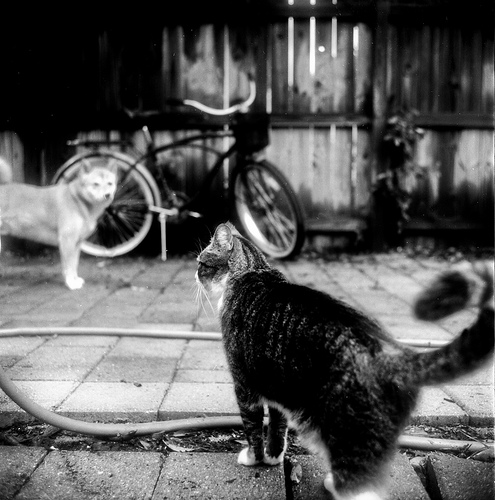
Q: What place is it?
A: It is a patio.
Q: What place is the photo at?
A: It is at the patio.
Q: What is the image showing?
A: It is showing a patio.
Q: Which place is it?
A: It is a patio.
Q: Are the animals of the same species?
A: No, they are dogs and cats.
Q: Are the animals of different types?
A: Yes, they are dogs and cats.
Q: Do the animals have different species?
A: Yes, they are dogs and cats.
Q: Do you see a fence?
A: Yes, there is a fence.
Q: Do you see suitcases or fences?
A: Yes, there is a fence.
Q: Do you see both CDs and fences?
A: No, there is a fence but no cds.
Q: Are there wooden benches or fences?
A: Yes, there is a wood fence.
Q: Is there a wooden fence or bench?
A: Yes, there is a wood fence.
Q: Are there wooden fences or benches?
A: Yes, there is a wood fence.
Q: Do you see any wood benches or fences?
A: Yes, there is a wood fence.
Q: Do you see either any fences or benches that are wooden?
A: Yes, the fence is wooden.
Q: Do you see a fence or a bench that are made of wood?
A: Yes, the fence is made of wood.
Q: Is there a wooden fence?
A: Yes, there is a wood fence.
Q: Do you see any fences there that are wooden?
A: Yes, there is a fence that is wooden.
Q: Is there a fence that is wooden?
A: Yes, there is a fence that is wooden.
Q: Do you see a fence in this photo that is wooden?
A: Yes, there is a fence that is wooden.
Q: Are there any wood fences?
A: Yes, there is a fence that is made of wood.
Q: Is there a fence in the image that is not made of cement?
A: Yes, there is a fence that is made of wood.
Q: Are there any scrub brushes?
A: No, there are no scrub brushes.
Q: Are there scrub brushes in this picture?
A: No, there are no scrub brushes.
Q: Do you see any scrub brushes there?
A: No, there are no scrub brushes.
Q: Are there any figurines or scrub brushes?
A: No, there are no scrub brushes or figurines.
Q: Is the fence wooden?
A: Yes, the fence is wooden.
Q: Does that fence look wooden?
A: Yes, the fence is wooden.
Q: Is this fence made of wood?
A: Yes, the fence is made of wood.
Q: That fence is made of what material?
A: The fence is made of wood.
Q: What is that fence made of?
A: The fence is made of wood.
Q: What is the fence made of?
A: The fence is made of wood.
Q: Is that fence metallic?
A: No, the fence is wooden.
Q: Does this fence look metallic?
A: No, the fence is wooden.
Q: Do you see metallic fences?
A: No, there is a fence but it is wooden.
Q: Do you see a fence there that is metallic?
A: No, there is a fence but it is wooden.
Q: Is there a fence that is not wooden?
A: No, there is a fence but it is wooden.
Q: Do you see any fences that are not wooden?
A: No, there is a fence but it is wooden.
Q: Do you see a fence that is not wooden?
A: No, there is a fence but it is wooden.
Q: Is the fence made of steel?
A: No, the fence is made of wood.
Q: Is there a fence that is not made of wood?
A: No, there is a fence but it is made of wood.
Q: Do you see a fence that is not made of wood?
A: No, there is a fence but it is made of wood.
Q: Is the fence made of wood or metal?
A: The fence is made of wood.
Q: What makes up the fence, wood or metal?
A: The fence is made of wood.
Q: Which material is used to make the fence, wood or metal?
A: The fence is made of wood.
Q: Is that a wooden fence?
A: Yes, that is a wooden fence.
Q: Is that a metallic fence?
A: No, that is a wooden fence.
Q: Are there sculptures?
A: No, there are no sculptures.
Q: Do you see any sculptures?
A: No, there are no sculptures.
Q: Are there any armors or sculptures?
A: No, there are no sculptures or armors.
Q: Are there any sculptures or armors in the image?
A: No, there are no sculptures or armors.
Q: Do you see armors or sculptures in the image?
A: No, there are no sculptures or armors.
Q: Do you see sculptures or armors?
A: No, there are no sculptures or armors.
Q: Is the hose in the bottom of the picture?
A: Yes, the hose is in the bottom of the image.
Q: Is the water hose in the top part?
A: No, the water hose is in the bottom of the image.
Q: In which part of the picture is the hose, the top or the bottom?
A: The hose is in the bottom of the image.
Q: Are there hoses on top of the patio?
A: Yes, there is a hose on top of the patio.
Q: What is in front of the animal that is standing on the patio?
A: The hose is in front of the cat.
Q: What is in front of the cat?
A: The hose is in front of the cat.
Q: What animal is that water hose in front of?
A: The water hose is in front of the cat.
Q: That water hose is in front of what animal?
A: The water hose is in front of the cat.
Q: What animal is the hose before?
A: The water hose is in front of the cat.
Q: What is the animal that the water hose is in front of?
A: The animal is a cat.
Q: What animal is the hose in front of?
A: The water hose is in front of the cat.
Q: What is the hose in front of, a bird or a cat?
A: The hose is in front of a cat.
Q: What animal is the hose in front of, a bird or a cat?
A: The hose is in front of a cat.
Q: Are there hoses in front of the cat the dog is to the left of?
A: Yes, there is a hose in front of the cat.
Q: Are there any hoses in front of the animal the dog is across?
A: Yes, there is a hose in front of the cat.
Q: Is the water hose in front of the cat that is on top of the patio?
A: Yes, the water hose is in front of the cat.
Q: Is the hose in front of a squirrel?
A: No, the hose is in front of the cat.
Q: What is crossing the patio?
A: The water hose is crossing the patio.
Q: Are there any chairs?
A: No, there are no chairs.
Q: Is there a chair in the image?
A: No, there are no chairs.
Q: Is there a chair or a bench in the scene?
A: No, there are no chairs or benches.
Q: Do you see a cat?
A: Yes, there is a cat.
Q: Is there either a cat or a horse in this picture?
A: Yes, there is a cat.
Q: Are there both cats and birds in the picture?
A: No, there is a cat but no birds.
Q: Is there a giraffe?
A: No, there are no giraffes.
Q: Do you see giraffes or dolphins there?
A: No, there are no giraffes or dolphins.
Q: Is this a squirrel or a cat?
A: This is a cat.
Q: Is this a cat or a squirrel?
A: This is a cat.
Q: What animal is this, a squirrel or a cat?
A: This is a cat.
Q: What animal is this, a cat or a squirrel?
A: This is a cat.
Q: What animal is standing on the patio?
A: The cat is standing on the patio.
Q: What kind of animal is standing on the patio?
A: The animal is a cat.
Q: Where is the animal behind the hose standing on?
A: The cat is standing on the patio.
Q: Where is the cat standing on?
A: The cat is standing on the patio.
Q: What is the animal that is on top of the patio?
A: The animal is a cat.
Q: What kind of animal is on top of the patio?
A: The animal is a cat.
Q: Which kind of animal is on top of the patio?
A: The animal is a cat.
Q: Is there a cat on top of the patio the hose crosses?
A: Yes, there is a cat on top of the patio.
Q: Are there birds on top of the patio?
A: No, there is a cat on top of the patio.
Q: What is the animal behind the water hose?
A: The animal is a cat.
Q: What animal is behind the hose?
A: The animal is a cat.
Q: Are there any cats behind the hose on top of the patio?
A: Yes, there is a cat behind the water hose.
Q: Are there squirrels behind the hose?
A: No, there is a cat behind the hose.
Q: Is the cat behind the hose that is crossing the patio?
A: Yes, the cat is behind the water hose.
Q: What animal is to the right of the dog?
A: The animal is a cat.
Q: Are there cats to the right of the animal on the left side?
A: Yes, there is a cat to the right of the dog.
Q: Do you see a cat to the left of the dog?
A: No, the cat is to the right of the dog.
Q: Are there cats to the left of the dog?
A: No, the cat is to the right of the dog.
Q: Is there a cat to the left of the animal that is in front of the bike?
A: No, the cat is to the right of the dog.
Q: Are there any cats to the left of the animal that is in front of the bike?
A: No, the cat is to the right of the dog.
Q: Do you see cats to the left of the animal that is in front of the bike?
A: No, the cat is to the right of the dog.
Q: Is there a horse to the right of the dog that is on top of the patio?
A: No, there is a cat to the right of the dog.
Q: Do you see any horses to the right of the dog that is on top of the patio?
A: No, there is a cat to the right of the dog.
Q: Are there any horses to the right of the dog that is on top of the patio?
A: No, there is a cat to the right of the dog.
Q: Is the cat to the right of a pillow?
A: No, the cat is to the right of the dog.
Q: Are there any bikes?
A: Yes, there is a bike.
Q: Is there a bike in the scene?
A: Yes, there is a bike.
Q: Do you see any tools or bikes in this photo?
A: Yes, there is a bike.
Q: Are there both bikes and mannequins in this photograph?
A: No, there is a bike but no mannequins.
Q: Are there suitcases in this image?
A: No, there are no suitcases.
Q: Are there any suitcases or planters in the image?
A: No, there are no suitcases or planters.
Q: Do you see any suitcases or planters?
A: No, there are no suitcases or planters.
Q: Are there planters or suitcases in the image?
A: No, there are no suitcases or planters.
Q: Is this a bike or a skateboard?
A: This is a bike.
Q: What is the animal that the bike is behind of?
A: The animal is a dog.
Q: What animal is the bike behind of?
A: The bike is behind the dog.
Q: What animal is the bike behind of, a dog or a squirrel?
A: The bike is behind a dog.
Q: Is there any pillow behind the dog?
A: No, there is a bike behind the dog.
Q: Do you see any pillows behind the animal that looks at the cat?
A: No, there is a bike behind the dog.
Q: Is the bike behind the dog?
A: Yes, the bike is behind the dog.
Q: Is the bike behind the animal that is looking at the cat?
A: Yes, the bike is behind the dog.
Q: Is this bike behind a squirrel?
A: No, the bike is behind the dog.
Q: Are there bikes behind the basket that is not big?
A: Yes, there is a bike behind the basket.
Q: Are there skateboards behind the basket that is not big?
A: No, there is a bike behind the basket.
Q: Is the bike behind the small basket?
A: Yes, the bike is behind the basket.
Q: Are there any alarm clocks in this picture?
A: No, there are no alarm clocks.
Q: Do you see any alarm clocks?
A: No, there are no alarm clocks.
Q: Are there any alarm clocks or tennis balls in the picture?
A: No, there are no alarm clocks or tennis balls.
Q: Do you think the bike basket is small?
A: Yes, the basket is small.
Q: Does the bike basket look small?
A: Yes, the basket is small.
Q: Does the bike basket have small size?
A: Yes, the basket is small.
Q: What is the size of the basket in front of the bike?
A: The basket is small.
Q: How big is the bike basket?
A: The basket is small.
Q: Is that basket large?
A: No, the basket is small.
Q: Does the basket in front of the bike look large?
A: No, the basket is small.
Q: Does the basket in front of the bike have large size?
A: No, the basket is small.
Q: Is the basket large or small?
A: The basket is small.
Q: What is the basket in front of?
A: The basket is in front of the bike.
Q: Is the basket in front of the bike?
A: Yes, the basket is in front of the bike.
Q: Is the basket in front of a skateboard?
A: No, the basket is in front of the bike.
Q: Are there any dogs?
A: Yes, there is a dog.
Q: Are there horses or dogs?
A: Yes, there is a dog.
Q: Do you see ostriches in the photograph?
A: No, there are no ostriches.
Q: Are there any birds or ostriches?
A: No, there are no ostriches or birds.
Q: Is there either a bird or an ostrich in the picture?
A: No, there are no ostriches or birds.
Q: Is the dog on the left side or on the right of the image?
A: The dog is on the left of the image.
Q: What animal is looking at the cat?
A: The dog is looking at the cat.